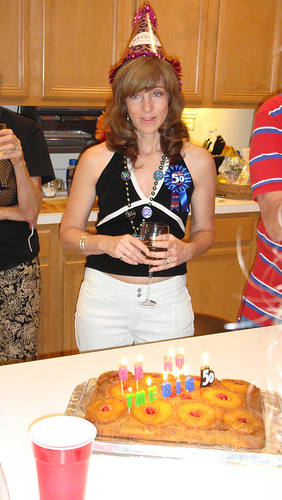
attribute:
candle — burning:
[177, 362, 237, 386]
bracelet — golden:
[79, 237, 86, 250]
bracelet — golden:
[75, 237, 83, 250]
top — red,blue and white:
[238, 94, 281, 327]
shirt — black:
[104, 182, 137, 215]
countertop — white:
[36, 192, 259, 227]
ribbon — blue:
[160, 162, 194, 214]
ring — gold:
[164, 259, 170, 265]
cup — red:
[24, 411, 100, 499]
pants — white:
[72, 266, 198, 352]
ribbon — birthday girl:
[161, 162, 192, 213]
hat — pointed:
[111, 6, 177, 60]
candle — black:
[197, 364, 217, 388]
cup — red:
[28, 414, 97, 498]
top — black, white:
[83, 133, 193, 276]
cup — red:
[33, 410, 102, 495]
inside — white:
[42, 413, 77, 430]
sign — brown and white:
[199, 360, 222, 396]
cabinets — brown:
[31, 6, 113, 100]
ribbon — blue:
[156, 160, 205, 228]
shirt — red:
[248, 94, 279, 323]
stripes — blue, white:
[237, 119, 277, 197]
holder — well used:
[195, 142, 223, 178]